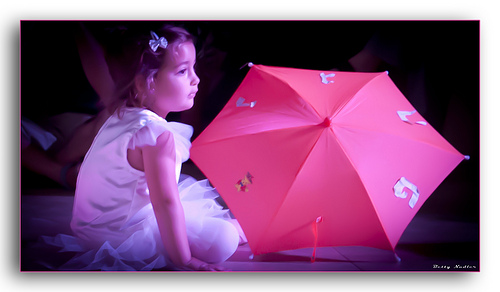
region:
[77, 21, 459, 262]
Thoughtful little girl pink umbrella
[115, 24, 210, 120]
Sweet face barrette hair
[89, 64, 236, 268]
Dancer white top tutu bottom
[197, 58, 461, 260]
Dark pink umbrella sits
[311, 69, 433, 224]
Special blue ribbons attached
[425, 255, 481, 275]
Photographer's name right corner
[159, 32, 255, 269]
Just waiting turn dance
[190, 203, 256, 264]
Ballet shoe behind knee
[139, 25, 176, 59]
Blue hair ribbon significant umbrella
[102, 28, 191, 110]
Soft brown hair frame face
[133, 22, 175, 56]
small pink ribbon in hair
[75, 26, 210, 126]
young girl with pink ribbon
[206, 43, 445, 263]
a pink umbrella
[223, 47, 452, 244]
pink umbrella with stickers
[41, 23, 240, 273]
young girl in pink dress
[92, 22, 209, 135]
young girl with curly hair and ribbon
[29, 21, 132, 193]
women sitting in background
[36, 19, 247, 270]
young girl in fluffy dress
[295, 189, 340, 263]
small ribbon on pink umbrella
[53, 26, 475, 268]
young girl sitting beside umbrella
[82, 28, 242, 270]
Young girl sitting on a stage.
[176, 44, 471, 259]
Red umbrella that it opened.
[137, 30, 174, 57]
Pretty clip with a bow attached to it.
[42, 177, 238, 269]
Girl wearing a white tutu.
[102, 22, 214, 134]
Girl with brown hair.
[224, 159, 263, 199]
Image on the umbrella.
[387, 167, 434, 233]
Sticker that is peeling off the umbrella.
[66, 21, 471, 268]
Young girl with a red umbrella.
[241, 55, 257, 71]
tip of umbrella covered for safety.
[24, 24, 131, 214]
Another person sitting on the stage in the background.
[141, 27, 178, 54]
a blue barrette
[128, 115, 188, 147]
white ruffle sleeve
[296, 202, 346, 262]
pink umbrella closure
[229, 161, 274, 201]
cartoon character surrounded by pink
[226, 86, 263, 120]
silver music note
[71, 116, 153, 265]
satin white dress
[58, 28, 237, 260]
little girl wearing white satin dress with ruffles and a blue barrette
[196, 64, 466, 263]
pink decorated umbrella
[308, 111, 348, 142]
top of an umbrella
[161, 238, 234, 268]
hand resting on floor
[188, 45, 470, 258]
a bright pink umbrella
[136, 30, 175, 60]
a small hair bow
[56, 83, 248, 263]
a satin white dress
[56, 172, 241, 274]
a simple white tutu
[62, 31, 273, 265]
a dressed up little girl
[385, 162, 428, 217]
a shiny silver sticker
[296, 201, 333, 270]
a small pink fastner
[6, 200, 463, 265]
a white tile floor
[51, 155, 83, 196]
a blue wrist band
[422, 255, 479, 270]
a white photographer label